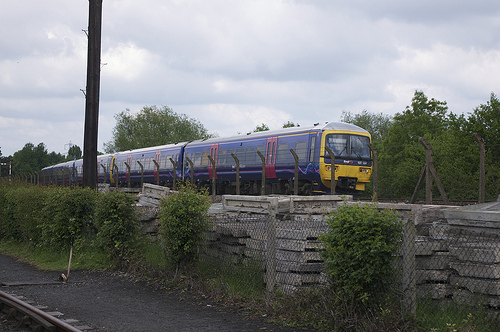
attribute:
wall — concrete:
[407, 176, 493, 326]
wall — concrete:
[396, 200, 471, 303]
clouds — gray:
[0, 0, 498, 158]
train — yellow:
[34, 122, 375, 189]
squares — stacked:
[98, 181, 498, 327]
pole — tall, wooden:
[76, 3, 126, 225]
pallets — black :
[79, 0, 491, 123]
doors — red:
[265, 134, 277, 184]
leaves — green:
[172, 195, 187, 212]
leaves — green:
[183, 202, 194, 217]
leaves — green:
[159, 217, 172, 227]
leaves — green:
[171, 222, 180, 241]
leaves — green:
[188, 227, 203, 248]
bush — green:
[0, 173, 105, 260]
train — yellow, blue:
[38, 123, 371, 200]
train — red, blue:
[39, 122, 403, 187]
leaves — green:
[393, 89, 455, 149]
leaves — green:
[462, 90, 499, 167]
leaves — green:
[340, 108, 391, 148]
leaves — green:
[112, 106, 209, 151]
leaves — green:
[67, 142, 82, 159]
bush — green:
[152, 174, 218, 286]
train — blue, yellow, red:
[40, 120, 379, 195]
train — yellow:
[85, 39, 396, 216]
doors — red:
[152, 137, 277, 177]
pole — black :
[43, 5, 135, 212]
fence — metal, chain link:
[39, 147, 478, 305]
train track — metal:
[0, 288, 94, 330]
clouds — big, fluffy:
[1, 7, 493, 167]